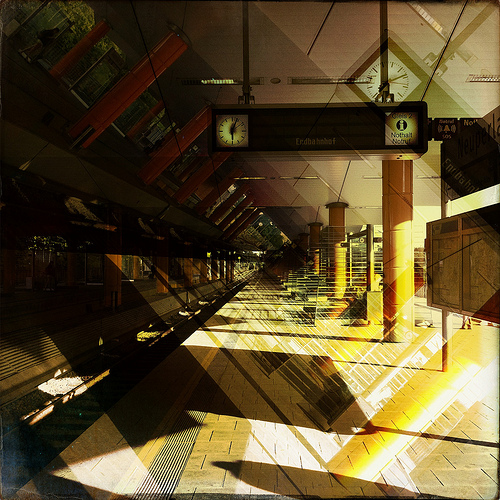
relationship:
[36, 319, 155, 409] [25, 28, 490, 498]
train tracks at train station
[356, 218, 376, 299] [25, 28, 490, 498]
support post at train station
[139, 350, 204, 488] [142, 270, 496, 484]
yellow stripe on train platform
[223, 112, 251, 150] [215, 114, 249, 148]
black hands on analog clock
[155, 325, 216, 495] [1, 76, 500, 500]
rubber padding at station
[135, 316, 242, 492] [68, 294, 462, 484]
steel grates on ground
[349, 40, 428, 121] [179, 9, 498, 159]
white clock on ceiling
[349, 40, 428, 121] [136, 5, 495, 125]
white clock at top of ceiling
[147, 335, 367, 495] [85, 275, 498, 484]
shadows are on floor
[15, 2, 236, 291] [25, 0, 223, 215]
roof has lots of windows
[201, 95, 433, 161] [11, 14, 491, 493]
sign tells name of station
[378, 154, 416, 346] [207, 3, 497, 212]
column holds up ceiling